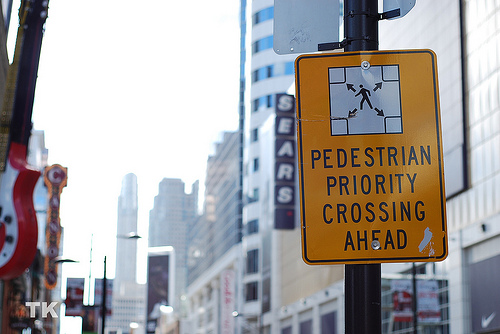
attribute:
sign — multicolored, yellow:
[295, 49, 449, 264]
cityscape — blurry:
[0, 0, 499, 333]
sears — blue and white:
[275, 94, 296, 206]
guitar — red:
[1, 0, 40, 282]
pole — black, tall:
[343, 1, 381, 332]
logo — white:
[25, 301, 60, 319]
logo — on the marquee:
[481, 311, 497, 329]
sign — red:
[44, 164, 70, 288]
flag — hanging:
[66, 276, 86, 317]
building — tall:
[240, 2, 355, 333]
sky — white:
[6, 0, 242, 332]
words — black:
[311, 146, 433, 250]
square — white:
[329, 63, 403, 136]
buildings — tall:
[1, 0, 500, 331]